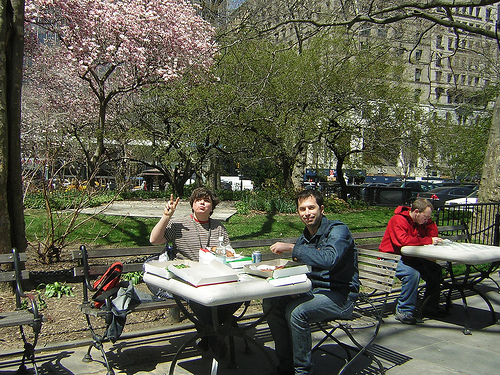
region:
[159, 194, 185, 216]
the peace sign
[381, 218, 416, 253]
man is wearing a red sweater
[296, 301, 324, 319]
man wearing blue jeans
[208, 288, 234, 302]
a table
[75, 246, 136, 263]
the brown bench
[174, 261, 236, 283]
books on the table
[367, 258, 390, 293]
a bench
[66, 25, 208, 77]
pink flowers on the tree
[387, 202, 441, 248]
man is sitting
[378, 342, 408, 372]
a shadow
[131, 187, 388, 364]
Two guys eating outside.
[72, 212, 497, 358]
A wooden park bench.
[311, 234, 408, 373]
A wooden chair.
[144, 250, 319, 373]
A white and black table.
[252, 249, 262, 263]
A blue can.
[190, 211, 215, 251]
A grey lanyard.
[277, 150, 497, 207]
Parked vehicles.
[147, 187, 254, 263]
A man giving a peace symbol with his hand.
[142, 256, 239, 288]
A white opened up cardboard box.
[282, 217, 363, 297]
A blue jacket.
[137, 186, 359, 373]
Two males at a table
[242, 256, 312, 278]
a white box of food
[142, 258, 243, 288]
an open white box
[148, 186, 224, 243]
boy holding up the peace sign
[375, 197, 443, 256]
man wearing a red sweatshirt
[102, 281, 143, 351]
a jean jacket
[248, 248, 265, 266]
a blue can of soda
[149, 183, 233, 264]
a young boy wearing a striped shirt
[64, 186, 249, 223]
a square cement slab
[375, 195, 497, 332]
a man sitting at a table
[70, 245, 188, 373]
a wooden park bench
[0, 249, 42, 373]
a wooden park bench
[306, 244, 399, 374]
a wooden park bench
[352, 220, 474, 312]
a wooden park bench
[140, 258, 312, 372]
a white park table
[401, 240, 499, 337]
a white park table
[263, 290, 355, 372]
a pair of blue jeans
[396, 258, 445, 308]
a pair of blue jeans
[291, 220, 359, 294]
a blue jean jacket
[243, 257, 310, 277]
a white pizza box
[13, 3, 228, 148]
Cherry blossom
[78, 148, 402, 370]
Two men sitting on the wooden bench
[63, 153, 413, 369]
Two men in the park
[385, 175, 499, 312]
A man in red hoodie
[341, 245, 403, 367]
Wooden bench in the park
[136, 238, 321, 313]
Food and drinks on the table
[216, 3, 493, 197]
Building in the background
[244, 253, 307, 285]
Food in the box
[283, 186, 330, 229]
Smiling face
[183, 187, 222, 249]
A man wearing a lanyard